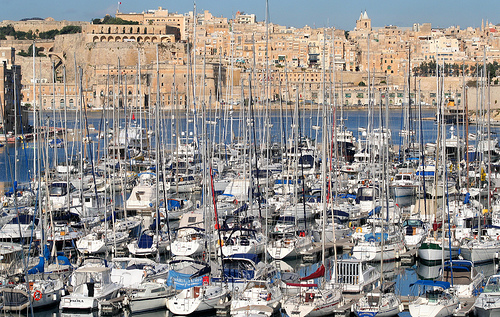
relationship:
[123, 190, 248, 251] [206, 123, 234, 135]
ships on sea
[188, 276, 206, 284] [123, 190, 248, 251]
masts over ships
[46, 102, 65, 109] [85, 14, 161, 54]
land under building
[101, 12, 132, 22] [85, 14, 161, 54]
trees above building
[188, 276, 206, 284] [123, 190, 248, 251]
masts of ships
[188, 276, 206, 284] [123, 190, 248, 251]
masts from ships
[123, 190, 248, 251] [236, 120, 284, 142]
ships in harbor